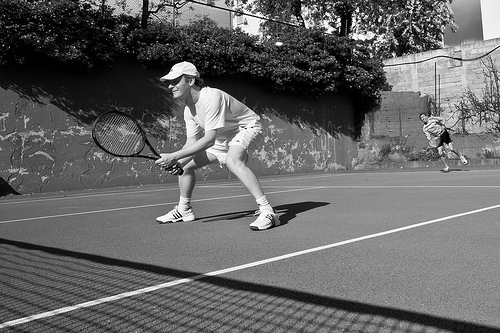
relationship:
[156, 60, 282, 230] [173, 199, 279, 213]
man wearing socks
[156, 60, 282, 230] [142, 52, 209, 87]
man wearing hat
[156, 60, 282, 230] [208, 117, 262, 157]
man wearing shorts